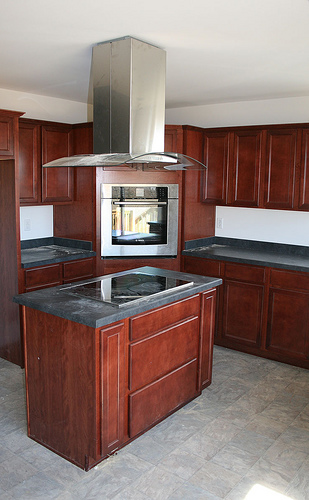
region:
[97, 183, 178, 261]
Oven in the kitchen.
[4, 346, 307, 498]
Tile floor in the kitchen.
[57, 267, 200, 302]
Range top in the island.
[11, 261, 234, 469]
Island in the middle of the kitchen.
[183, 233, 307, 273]
Counter space in the kitchen.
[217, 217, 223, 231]
Outlet in the kitchen.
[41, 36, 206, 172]
Metal and glass hood in the kitchen.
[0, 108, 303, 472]
Dark red cabinets in the kitchen.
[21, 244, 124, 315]
Dust on the countertop.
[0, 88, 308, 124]
Wall above the cabinets.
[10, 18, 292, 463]
kitchen decorated with reddish-brown wood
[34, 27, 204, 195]
large silver vent attached to ceiling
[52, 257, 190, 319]
dark cooking surface on kitchen island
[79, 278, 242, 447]
rectangular panels on wide side of kitchen island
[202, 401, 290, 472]
floor covered in tiles of mixed greys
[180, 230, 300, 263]
black stone counter tops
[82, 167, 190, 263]
oven set into middle of wall in a corner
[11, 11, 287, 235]
white ceiling and walls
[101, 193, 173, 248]
reflection on oven door of yellow structure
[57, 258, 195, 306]
reflection on cook top of oven door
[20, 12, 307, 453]
picture taken indoors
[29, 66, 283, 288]
picture taken during the day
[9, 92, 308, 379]
A large kitchen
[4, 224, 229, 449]
An Island in the middle of the kitchen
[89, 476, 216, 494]
The floors are tile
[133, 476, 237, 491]
The tiles are silver in color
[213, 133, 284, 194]
The cupboards are wood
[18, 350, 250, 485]
The oven is in the middle of the island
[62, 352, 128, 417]
The wood is dark brown in color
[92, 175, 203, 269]
The oven is set into the furniture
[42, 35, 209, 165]
chrome colored stove hood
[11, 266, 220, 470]
cook top on some cabinets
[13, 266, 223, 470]
island cooking top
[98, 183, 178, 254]
chrome colored oven with buttons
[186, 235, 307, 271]
a marble counter top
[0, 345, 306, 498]
a light colored tile floor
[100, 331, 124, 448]
left cupboard door of island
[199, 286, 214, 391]
right cupboard door of island cooktop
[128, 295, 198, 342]
top drawer of island cook top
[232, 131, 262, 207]
a cupboard door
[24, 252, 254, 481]
kitchen island in the kitchen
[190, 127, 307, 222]
kitchen cabinets for storage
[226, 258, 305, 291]
kitchen drawer for storage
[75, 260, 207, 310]
kitchen stove on island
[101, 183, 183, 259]
oven for cooking in the kitchen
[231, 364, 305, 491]
grey floor tiles in the kitchen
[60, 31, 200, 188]
kitchen smoke chimney for ventilation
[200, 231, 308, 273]
grey kitchen counter of cooking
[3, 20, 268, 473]
a very net kitchen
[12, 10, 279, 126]
white clear kitchen ceiling